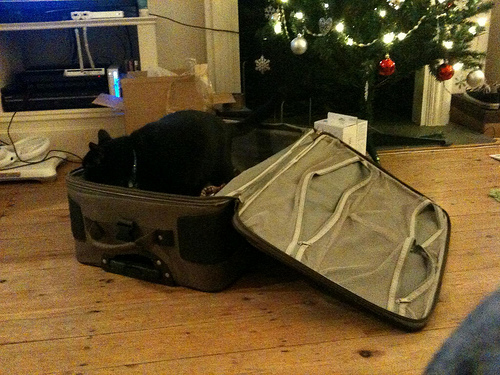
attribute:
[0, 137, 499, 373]
floor — beneath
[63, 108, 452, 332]
suitcase — open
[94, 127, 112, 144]
ear — black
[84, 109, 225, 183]
cat — inside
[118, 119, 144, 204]
collar — black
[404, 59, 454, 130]
package — small, under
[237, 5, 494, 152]
christmas tree — behind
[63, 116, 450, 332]
luggage — black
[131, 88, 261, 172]
cat — black 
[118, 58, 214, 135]
box — brown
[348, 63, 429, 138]
base — green